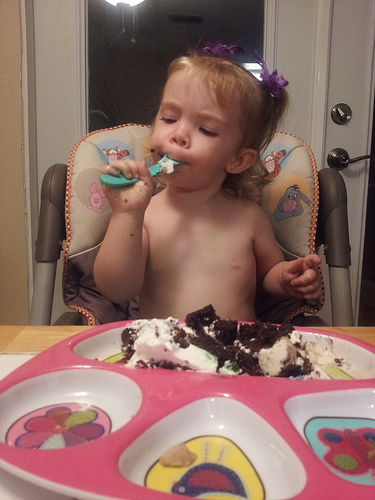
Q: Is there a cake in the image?
A: Yes, there is a cake.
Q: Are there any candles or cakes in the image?
A: Yes, there is a cake.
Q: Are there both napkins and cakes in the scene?
A: No, there is a cake but no napkins.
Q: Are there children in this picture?
A: Yes, there is a child.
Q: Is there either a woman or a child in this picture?
A: Yes, there is a child.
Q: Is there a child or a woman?
A: Yes, there is a child.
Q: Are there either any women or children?
A: Yes, there is a child.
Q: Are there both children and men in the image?
A: No, there is a child but no men.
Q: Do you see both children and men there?
A: No, there is a child but no men.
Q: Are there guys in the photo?
A: No, there are no guys.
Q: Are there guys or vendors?
A: No, there are no guys or vendors.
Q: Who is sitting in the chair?
A: The child is sitting in the chair.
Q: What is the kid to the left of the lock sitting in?
A: The child is sitting in the chair.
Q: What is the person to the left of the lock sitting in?
A: The child is sitting in the chair.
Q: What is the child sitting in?
A: The child is sitting in the chair.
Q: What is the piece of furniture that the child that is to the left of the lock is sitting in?
A: The piece of furniture is a chair.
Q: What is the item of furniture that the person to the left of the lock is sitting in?
A: The piece of furniture is a chair.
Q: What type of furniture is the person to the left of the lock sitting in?
A: The kid is sitting in the chair.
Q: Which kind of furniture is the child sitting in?
A: The kid is sitting in the chair.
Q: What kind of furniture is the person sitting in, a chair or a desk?
A: The kid is sitting in a chair.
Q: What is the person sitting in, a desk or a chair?
A: The kid is sitting in a chair.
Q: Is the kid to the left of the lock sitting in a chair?
A: Yes, the kid is sitting in a chair.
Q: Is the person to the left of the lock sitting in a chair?
A: Yes, the kid is sitting in a chair.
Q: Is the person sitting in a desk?
A: No, the child is sitting in a chair.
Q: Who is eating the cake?
A: The child is eating the cake.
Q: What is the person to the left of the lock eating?
A: The child is eating a cake.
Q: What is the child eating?
A: The child is eating a cake.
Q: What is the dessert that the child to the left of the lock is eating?
A: The dessert is a cake.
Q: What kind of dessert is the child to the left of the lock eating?
A: The child is eating a cake.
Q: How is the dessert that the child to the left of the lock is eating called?
A: The dessert is a cake.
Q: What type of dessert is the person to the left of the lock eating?
A: The child is eating a cake.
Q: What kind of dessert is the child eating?
A: The child is eating a cake.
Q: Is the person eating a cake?
A: Yes, the child is eating a cake.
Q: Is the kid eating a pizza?
A: No, the kid is eating a cake.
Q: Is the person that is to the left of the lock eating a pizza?
A: No, the kid is eating a cake.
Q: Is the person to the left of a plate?
A: No, the child is to the left of the lock.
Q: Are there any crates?
A: No, there are no crates.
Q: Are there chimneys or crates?
A: No, there are no crates or chimneys.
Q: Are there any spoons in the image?
A: Yes, there is a spoon.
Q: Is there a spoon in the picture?
A: Yes, there is a spoon.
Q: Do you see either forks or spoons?
A: Yes, there is a spoon.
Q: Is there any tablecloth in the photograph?
A: No, there are no tablecloths.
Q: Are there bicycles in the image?
A: No, there are no bicycles.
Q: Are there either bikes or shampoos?
A: No, there are no bikes or shampoos.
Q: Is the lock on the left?
A: No, the lock is on the right of the image.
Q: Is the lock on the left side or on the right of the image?
A: The lock is on the right of the image.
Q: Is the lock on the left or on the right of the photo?
A: The lock is on the right of the image.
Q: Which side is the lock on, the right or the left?
A: The lock is on the right of the image.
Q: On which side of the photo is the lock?
A: The lock is on the right of the image.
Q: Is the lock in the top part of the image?
A: Yes, the lock is in the top of the image.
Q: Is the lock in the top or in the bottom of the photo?
A: The lock is in the top of the image.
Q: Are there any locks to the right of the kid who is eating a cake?
A: Yes, there is a lock to the right of the kid.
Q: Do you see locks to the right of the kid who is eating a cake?
A: Yes, there is a lock to the right of the kid.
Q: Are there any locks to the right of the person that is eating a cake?
A: Yes, there is a lock to the right of the kid.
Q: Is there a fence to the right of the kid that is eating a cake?
A: No, there is a lock to the right of the kid.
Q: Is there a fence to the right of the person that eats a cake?
A: No, there is a lock to the right of the kid.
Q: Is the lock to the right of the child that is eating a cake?
A: Yes, the lock is to the right of the kid.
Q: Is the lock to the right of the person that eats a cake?
A: Yes, the lock is to the right of the kid.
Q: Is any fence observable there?
A: No, there are no fences.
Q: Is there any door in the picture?
A: Yes, there is a door.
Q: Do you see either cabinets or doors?
A: Yes, there is a door.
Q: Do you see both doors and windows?
A: Yes, there are both a door and a window.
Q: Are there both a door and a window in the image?
A: Yes, there are both a door and a window.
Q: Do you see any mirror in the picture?
A: No, there are no mirrors.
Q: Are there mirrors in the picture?
A: No, there are no mirrors.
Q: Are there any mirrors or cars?
A: No, there are no mirrors or cars.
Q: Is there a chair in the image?
A: Yes, there is a chair.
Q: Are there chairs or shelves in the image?
A: Yes, there is a chair.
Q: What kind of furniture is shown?
A: The furniture is a chair.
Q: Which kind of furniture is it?
A: The piece of furniture is a chair.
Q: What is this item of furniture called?
A: This is a chair.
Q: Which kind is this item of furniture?
A: This is a chair.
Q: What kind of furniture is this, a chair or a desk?
A: This is a chair.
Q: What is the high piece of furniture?
A: The piece of furniture is a chair.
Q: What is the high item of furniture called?
A: The piece of furniture is a chair.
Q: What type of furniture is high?
A: The furniture is a chair.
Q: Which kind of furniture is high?
A: The furniture is a chair.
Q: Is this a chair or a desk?
A: This is a chair.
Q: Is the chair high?
A: Yes, the chair is high.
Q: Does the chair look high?
A: Yes, the chair is high.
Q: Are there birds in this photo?
A: Yes, there is a bird.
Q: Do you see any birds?
A: Yes, there is a bird.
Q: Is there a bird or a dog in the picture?
A: Yes, there is a bird.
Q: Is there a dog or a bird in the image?
A: Yes, there is a bird.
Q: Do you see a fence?
A: No, there are no fences.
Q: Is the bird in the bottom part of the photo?
A: Yes, the bird is in the bottom of the image.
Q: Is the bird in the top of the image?
A: No, the bird is in the bottom of the image.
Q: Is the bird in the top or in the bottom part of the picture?
A: The bird is in the bottom of the image.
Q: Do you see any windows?
A: Yes, there is a window.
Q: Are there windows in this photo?
A: Yes, there is a window.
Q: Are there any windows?
A: Yes, there is a window.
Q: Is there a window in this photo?
A: Yes, there is a window.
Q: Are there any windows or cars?
A: Yes, there is a window.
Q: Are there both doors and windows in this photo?
A: Yes, there are both a window and a door.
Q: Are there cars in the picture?
A: No, there are no cars.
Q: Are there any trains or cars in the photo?
A: No, there are no cars or trains.